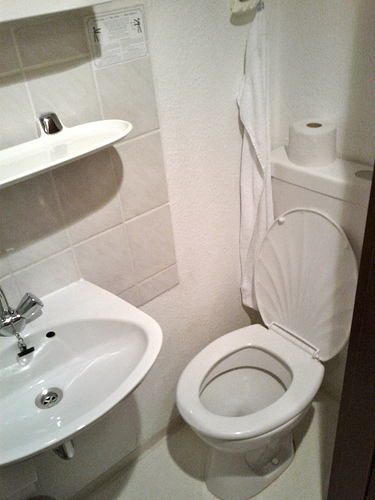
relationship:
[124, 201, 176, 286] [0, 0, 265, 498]
tile on wall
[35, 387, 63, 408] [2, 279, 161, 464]
drain in sink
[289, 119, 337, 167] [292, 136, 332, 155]
roll of toilet paper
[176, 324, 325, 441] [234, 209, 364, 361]
seat with lid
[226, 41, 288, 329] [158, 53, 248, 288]
towel hanging on wall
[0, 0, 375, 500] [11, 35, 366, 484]
bathroom of bathroom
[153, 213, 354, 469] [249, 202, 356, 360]
toilet with lid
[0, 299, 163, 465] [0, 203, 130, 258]
bathroom sink attached to wall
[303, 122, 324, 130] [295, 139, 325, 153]
roll of toilet paper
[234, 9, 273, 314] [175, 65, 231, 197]
towel hanging from wall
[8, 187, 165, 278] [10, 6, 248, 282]
bathroom wall on bathroom wall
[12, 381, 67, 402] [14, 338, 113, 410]
drain in sink bottom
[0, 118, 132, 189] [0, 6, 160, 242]
counter shelf hanging on wall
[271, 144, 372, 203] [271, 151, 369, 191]
cover on top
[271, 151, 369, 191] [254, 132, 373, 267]
top of tank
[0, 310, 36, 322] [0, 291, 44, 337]
knob on bathroom faucet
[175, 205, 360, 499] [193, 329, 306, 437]
toilet has seat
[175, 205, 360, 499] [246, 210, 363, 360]
toilet has lid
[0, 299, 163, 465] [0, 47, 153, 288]
bathroom sink mounted to wall